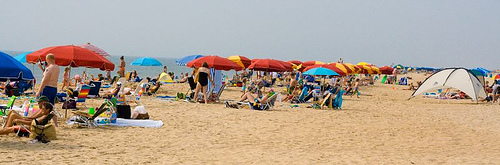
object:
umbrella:
[24, 43, 115, 72]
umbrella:
[128, 56, 164, 67]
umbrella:
[301, 65, 341, 76]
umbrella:
[245, 58, 296, 73]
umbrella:
[302, 60, 327, 67]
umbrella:
[185, 55, 244, 72]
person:
[33, 53, 60, 107]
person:
[115, 55, 127, 76]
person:
[59, 65, 74, 90]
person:
[0, 103, 57, 135]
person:
[191, 61, 216, 105]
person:
[236, 88, 276, 107]